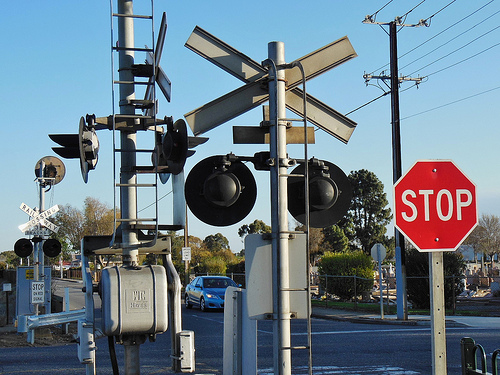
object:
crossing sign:
[18, 202, 61, 234]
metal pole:
[426, 247, 447, 374]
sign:
[393, 158, 478, 252]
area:
[1, 0, 500, 375]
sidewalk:
[0, 288, 500, 375]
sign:
[182, 24, 358, 145]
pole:
[265, 39, 293, 374]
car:
[184, 275, 242, 311]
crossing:
[0, 289, 499, 374]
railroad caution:
[0, 2, 499, 375]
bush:
[316, 248, 379, 302]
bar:
[73, 232, 96, 374]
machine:
[100, 262, 170, 342]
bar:
[115, 0, 139, 264]